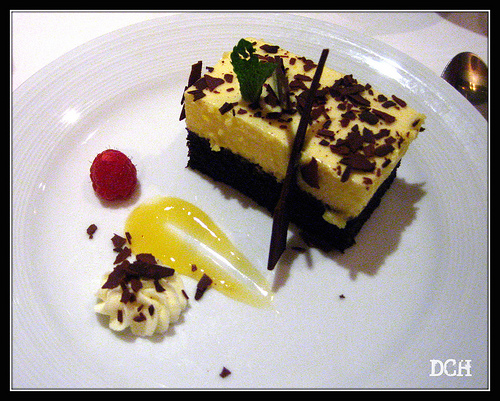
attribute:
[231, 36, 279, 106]
garnish — green, twig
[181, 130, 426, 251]
cake — square cut, yellow, chocolate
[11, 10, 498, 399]
plate — white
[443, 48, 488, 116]
spoon — silver, shiney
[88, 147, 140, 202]
raspberry — fresh, red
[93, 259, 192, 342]
cream — dollop, swish, dallop, white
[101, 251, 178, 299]
shavings — chocolate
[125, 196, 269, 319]
gel — yellow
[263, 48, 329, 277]
shaving — long, chocolate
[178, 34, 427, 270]
cake — rectangular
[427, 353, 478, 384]
dch — white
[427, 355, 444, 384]
d — white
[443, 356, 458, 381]
c — white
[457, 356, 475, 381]
h — white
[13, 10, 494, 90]
table — white